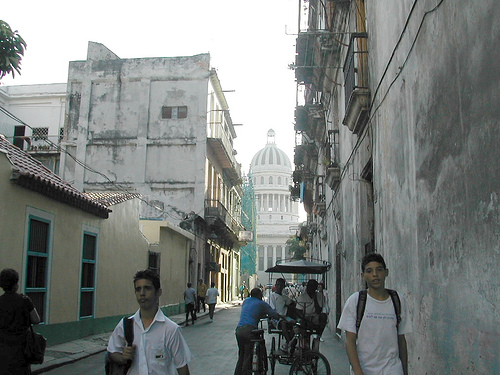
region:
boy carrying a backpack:
[345, 256, 442, 373]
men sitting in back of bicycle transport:
[263, 246, 335, 364]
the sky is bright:
[226, 28, 293, 147]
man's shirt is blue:
[233, 282, 275, 340]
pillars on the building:
[246, 228, 318, 268]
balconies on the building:
[202, 193, 261, 248]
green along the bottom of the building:
[39, 318, 131, 340]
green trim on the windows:
[18, 198, 107, 332]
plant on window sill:
[312, 153, 341, 178]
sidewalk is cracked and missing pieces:
[48, 337, 102, 367]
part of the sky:
[218, 18, 283, 75]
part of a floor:
[189, 328, 211, 366]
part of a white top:
[357, 292, 389, 360]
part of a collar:
[130, 305, 152, 330]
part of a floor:
[210, 317, 235, 339]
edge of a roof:
[273, 250, 316, 285]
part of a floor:
[199, 330, 226, 364]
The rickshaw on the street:
[249, 248, 339, 374]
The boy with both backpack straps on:
[338, 246, 415, 374]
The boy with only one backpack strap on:
[95, 268, 192, 373]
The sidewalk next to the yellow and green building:
[33, 295, 244, 374]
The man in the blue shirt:
[231, 283, 276, 373]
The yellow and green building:
[0, 134, 194, 346]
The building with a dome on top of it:
[237, 124, 307, 289]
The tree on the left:
[0, 18, 31, 87]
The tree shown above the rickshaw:
[278, 225, 316, 265]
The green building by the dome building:
[233, 171, 258, 296]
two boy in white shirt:
[31, 188, 496, 353]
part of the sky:
[248, 5, 279, 70]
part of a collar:
[146, 297, 168, 344]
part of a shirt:
[136, 335, 164, 370]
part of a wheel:
[306, 342, 333, 364]